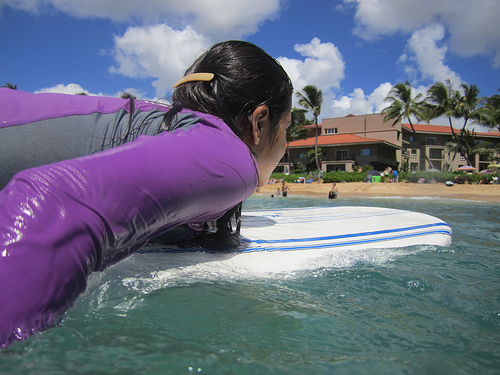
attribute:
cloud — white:
[313, 37, 380, 66]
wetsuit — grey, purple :
[2, 73, 262, 373]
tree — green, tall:
[387, 80, 451, 118]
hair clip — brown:
[171, 72, 215, 88]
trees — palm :
[377, 74, 499, 171]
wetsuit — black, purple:
[4, 81, 256, 326]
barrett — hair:
[160, 71, 223, 97]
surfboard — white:
[76, 192, 453, 295]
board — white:
[259, 187, 471, 280]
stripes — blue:
[137, 219, 450, 254]